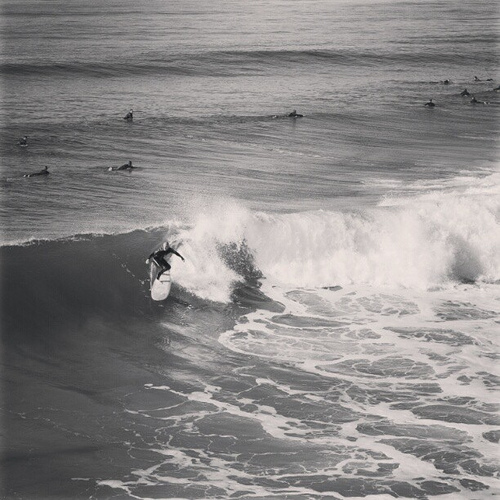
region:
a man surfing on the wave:
[132, 230, 198, 305]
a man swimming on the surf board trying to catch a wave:
[97, 155, 147, 177]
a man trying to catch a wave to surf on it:
[6, 153, 56, 188]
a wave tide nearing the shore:
[9, 8, 432, 88]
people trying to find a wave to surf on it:
[407, 60, 495, 118]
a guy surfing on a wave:
[14, 221, 481, 313]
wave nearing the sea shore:
[199, 184, 489, 406]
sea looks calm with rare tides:
[3, 0, 496, 45]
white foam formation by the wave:
[226, 296, 496, 484]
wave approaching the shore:
[195, 185, 498, 484]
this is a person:
[134, 228, 219, 312]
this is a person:
[107, 150, 179, 210]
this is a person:
[22, 144, 76, 221]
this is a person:
[108, 109, 158, 134]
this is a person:
[275, 90, 318, 157]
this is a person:
[398, 85, 448, 142]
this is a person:
[437, 75, 462, 96]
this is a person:
[462, 95, 489, 150]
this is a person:
[472, 58, 487, 105]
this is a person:
[434, 73, 451, 101]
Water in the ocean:
[173, 14, 293, 103]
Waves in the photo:
[262, 216, 375, 301]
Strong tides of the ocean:
[282, 212, 474, 287]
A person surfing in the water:
[140, 222, 200, 322]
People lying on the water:
[13, 149, 163, 185]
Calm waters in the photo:
[150, 4, 290, 39]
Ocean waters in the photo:
[230, 328, 441, 456]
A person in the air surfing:
[147, 235, 190, 300]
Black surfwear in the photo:
[152, 245, 183, 285]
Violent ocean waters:
[217, 216, 322, 284]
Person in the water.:
[87, 219, 229, 326]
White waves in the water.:
[171, 332, 371, 498]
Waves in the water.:
[122, 292, 367, 474]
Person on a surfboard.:
[103, 205, 223, 313]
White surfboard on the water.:
[112, 237, 212, 318]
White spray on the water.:
[206, 167, 373, 319]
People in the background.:
[28, 95, 213, 227]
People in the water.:
[352, 42, 487, 138]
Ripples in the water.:
[169, 308, 391, 473]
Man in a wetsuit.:
[129, 220, 243, 328]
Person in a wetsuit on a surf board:
[140, 238, 183, 303]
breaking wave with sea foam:
[1, 190, 499, 291]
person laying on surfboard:
[104, 150, 140, 180]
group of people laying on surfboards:
[416, 68, 496, 118]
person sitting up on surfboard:
[119, 106, 144, 128]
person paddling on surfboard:
[270, 104, 306, 129]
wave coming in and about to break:
[1, 39, 494, 76]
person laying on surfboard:
[21, 158, 60, 186]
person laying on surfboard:
[8, 133, 35, 150]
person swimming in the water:
[419, 95, 439, 110]